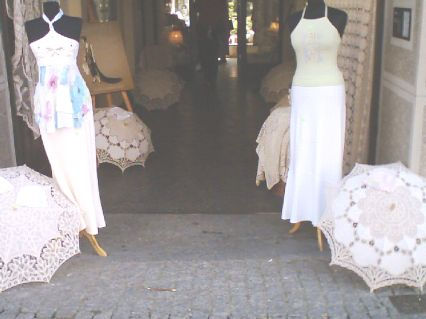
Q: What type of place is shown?
A: It is a store.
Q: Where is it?
A: This is at the store.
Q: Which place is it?
A: It is a store.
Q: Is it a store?
A: Yes, it is a store.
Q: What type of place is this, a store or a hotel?
A: It is a store.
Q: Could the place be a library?
A: No, it is a store.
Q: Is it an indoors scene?
A: Yes, it is indoors.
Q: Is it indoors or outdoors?
A: It is indoors.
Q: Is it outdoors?
A: No, it is indoors.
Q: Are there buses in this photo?
A: No, there are no buses.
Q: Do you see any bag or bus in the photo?
A: No, there are no buses or bags.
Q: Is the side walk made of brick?
A: Yes, the side walk is made of brick.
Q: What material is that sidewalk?
A: The sidewalk is made of brick.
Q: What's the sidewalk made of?
A: The sidewalk is made of brick.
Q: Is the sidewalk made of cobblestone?
A: No, the sidewalk is made of brick.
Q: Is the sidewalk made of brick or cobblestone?
A: The sidewalk is made of brick.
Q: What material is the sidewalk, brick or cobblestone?
A: The sidewalk is made of brick.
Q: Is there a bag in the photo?
A: No, there are no bags.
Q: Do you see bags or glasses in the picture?
A: No, there are no bags or glasses.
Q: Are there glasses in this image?
A: No, there are no glasses.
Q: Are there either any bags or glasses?
A: No, there are no glasses or bags.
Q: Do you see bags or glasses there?
A: No, there are no glasses or bags.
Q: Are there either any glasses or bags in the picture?
A: No, there are no glasses or bags.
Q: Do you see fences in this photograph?
A: No, there are no fences.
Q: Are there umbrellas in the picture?
A: Yes, there is an umbrella.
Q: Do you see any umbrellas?
A: Yes, there is an umbrella.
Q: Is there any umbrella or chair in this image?
A: Yes, there is an umbrella.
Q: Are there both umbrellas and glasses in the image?
A: No, there is an umbrella but no glasses.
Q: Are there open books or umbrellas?
A: Yes, there is an open umbrella.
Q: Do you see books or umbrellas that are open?
A: Yes, the umbrella is open.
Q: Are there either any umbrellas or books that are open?
A: Yes, the umbrella is open.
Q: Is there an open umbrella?
A: Yes, there is an open umbrella.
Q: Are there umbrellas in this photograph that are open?
A: Yes, there is an umbrella that is open.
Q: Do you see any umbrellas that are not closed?
A: Yes, there is a open umbrella.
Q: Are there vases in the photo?
A: No, there are no vases.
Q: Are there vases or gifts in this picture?
A: No, there are no vases or gifts.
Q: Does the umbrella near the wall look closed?
A: No, the umbrella is open.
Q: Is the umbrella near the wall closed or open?
A: The umbrella is open.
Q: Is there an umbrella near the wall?
A: Yes, there is an umbrella near the wall.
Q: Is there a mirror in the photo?
A: No, there are no mirrors.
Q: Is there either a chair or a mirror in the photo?
A: No, there are no mirrors or chairs.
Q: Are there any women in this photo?
A: Yes, there is a woman.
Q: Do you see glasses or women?
A: Yes, there is a woman.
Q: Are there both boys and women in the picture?
A: No, there is a woman but no boys.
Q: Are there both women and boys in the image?
A: No, there is a woman but no boys.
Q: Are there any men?
A: No, there are no men.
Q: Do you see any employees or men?
A: No, there are no men or employees.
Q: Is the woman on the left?
A: Yes, the woman is on the left of the image.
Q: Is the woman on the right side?
A: No, the woman is on the left of the image.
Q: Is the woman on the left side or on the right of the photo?
A: The woman is on the left of the image.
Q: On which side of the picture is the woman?
A: The woman is on the left of the image.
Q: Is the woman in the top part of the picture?
A: Yes, the woman is in the top of the image.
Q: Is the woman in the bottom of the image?
A: No, the woman is in the top of the image.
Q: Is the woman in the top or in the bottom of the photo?
A: The woman is in the top of the image.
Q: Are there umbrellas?
A: Yes, there is an umbrella.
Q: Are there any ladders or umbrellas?
A: Yes, there is an umbrella.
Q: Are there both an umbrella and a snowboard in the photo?
A: No, there is an umbrella but no snowboards.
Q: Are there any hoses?
A: No, there are no hoses.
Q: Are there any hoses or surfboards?
A: No, there are no hoses or surfboards.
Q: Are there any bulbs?
A: No, there are no bulbs.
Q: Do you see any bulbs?
A: No, there are no bulbs.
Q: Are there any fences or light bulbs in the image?
A: No, there are no light bulbs or fences.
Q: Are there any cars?
A: No, there are no cars.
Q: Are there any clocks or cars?
A: No, there are no cars or clocks.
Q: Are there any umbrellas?
A: Yes, there is an umbrella.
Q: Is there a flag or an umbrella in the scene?
A: Yes, there is an umbrella.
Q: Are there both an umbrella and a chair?
A: No, there is an umbrella but no chairs.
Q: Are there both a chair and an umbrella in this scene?
A: No, there is an umbrella but no chairs.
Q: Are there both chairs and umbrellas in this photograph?
A: No, there is an umbrella but no chairs.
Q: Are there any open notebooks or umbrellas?
A: Yes, there is an open umbrella.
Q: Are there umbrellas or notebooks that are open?
A: Yes, the umbrella is open.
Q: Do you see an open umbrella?
A: Yes, there is an open umbrella.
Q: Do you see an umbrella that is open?
A: Yes, there is an umbrella that is open.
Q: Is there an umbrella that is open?
A: Yes, there is an umbrella that is open.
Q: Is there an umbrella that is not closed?
A: Yes, there is a open umbrella.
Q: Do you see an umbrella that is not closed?
A: Yes, there is a open umbrella.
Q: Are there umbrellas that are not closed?
A: Yes, there is a open umbrella.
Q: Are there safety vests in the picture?
A: No, there are no safety vests.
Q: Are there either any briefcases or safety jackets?
A: No, there are no safety jackets or briefcases.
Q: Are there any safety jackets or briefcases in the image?
A: No, there are no safety jackets or briefcases.